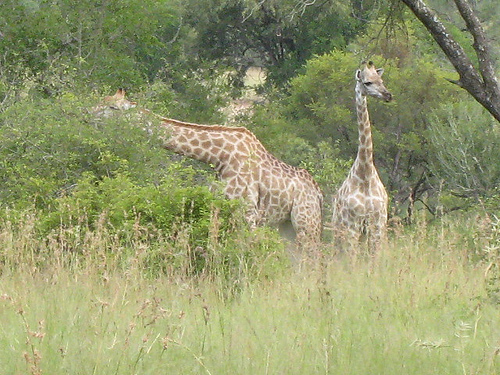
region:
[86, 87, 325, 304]
a giraffe grazing in the tall grass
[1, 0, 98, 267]
thick woods in the background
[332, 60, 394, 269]
a giraffe foraging in the wood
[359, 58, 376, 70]
the giraffes hairy horns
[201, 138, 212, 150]
a giraffes brown spot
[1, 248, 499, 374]
tall grazing grass in the plains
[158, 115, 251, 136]
brown mane on the back of the neck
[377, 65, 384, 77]
white ears of the giraffe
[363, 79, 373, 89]
dark eyes of the giraffe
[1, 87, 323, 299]
a giraffe feeding on leaves of a bush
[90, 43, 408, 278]
two giraffes standing in a field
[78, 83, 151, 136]
a giraffe eating leaves off a bush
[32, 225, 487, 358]
tall grass in an open field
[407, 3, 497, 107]
braches of a tree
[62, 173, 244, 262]
a bush growing up from the ground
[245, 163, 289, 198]
giraffe's spotted coat of fur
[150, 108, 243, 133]
the brown main on a giraffe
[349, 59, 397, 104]
giraffe looking to the right/his left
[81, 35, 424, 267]
two giraffes standing in an open field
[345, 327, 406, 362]
green grass in an open field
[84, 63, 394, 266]
two giraffes grazing in field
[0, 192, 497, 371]
tall grass gone to seed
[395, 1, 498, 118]
tree branches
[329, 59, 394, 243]
brown and white giraffe on alert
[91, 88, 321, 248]
giraffe grazing on short tree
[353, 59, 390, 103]
giraffe head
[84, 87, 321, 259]
giraffe with neck stretched out to feed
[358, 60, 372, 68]
giraffe horns on top of head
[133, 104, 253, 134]
stubbly bristly short giraffe mane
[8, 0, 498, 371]
two giraffes in outdoor habitat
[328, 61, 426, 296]
A tall brown and white giraffe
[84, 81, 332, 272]
A tall brown and white giraffe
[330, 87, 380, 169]
A tall brown and white giraffe's neck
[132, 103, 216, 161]
A tall brown and white giraffe's neck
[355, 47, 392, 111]
A tall brown and white giraffe's head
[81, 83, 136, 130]
A tall brown and white giraffe's head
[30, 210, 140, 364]
tall brown and green grass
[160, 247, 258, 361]
tall brown and green grass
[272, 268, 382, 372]
tall brown and green grass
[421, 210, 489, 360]
tall brown and green grass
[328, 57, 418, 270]
this is a giraffe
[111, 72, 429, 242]
the giraffes are two in number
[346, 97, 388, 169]
this is the neck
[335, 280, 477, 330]
this is the grass area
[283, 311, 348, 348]
the grass is green in color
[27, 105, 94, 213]
this is a tree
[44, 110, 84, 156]
the leaves are green in color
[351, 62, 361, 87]
this is a nose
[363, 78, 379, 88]
this is a the eye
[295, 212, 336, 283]
this is the leg